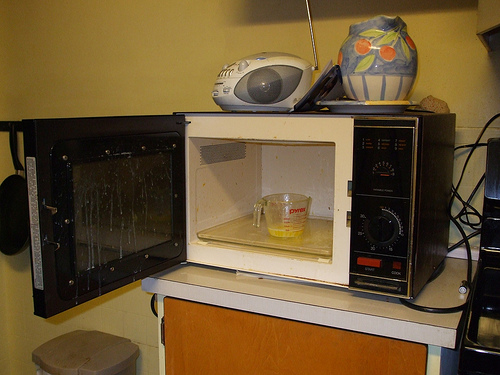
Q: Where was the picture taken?
A: In a kitchen.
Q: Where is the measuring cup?
A: In microwave.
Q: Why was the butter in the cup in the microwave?
A: To melt.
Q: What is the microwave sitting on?
A: A cabinet.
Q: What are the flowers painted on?
A: A vase.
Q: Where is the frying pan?
A: On wall.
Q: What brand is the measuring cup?
A: Pyrex.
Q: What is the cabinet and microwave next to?
A: A oven.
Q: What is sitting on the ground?
A: A trash can.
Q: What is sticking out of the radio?
A: Antenna.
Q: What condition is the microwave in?
A: Dirty.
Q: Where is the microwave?
A: Counter top.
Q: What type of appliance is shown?
A: Microwave.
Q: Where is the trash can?
A: Left side of the cabinet.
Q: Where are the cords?
A: Right side of the microwave.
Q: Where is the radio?
A: On top of the microwave.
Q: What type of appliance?
A: Microwave.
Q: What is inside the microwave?
A: Measuring cup.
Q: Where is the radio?
A: On top of the microwave.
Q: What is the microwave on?
A: The counter.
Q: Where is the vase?
A: On top of the microwave.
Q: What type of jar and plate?
A: Porcelain.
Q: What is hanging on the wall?
A: Pan.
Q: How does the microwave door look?
A: Dirty.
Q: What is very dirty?
A: The microwave door.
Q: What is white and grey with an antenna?
A: Radio.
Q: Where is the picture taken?
A: A kitchen.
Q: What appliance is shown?
A: Microwave.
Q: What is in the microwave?
A: Measuring cup.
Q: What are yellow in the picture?
A: Walls.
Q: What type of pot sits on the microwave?
A: Plant.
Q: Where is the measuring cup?
A: Microwave.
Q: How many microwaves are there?
A: One.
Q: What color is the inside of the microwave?
A: White.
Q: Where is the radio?
A: On top of microwave.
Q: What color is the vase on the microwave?
A: Blue, orange and white.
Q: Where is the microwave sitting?
A: The counter.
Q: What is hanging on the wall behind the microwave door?
A: A pan.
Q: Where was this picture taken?
A: Kitchen.